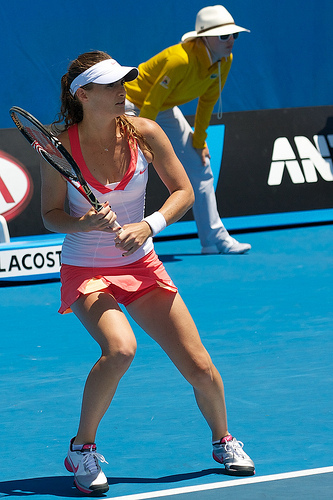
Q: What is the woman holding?
A: A tennis racket.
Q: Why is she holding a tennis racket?
A: She is preparing to hit the ball.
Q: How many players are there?
A: One.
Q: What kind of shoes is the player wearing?
A: Tennis shoes.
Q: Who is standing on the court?
A: Women.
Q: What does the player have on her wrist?
A: A wristband.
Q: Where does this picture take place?
A: On a tennis court.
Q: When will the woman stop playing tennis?
A: When the game is over.